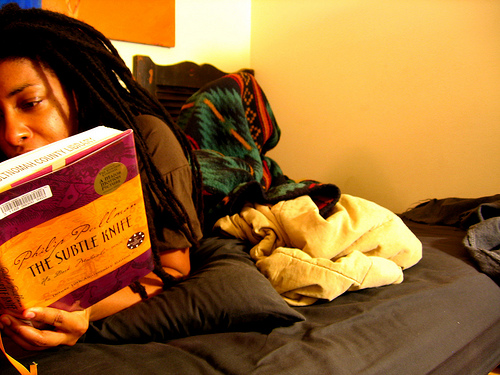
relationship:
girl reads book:
[0, 4, 211, 369] [0, 111, 162, 346]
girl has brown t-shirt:
[0, 4, 211, 369] [105, 111, 213, 251]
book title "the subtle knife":
[0, 111, 162, 346] [22, 211, 141, 282]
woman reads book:
[0, 4, 211, 369] [0, 111, 162, 346]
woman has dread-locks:
[0, 4, 211, 369] [1, 2, 208, 303]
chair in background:
[123, 46, 272, 133] [67, 6, 493, 93]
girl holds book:
[0, 4, 211, 369] [0, 111, 162, 346]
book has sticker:
[0, 111, 162, 346] [88, 160, 131, 198]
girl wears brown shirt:
[0, 4, 211, 369] [105, 111, 213, 251]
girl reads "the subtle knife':
[0, 4, 211, 369] [22, 211, 141, 282]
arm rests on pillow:
[71, 117, 210, 349] [51, 226, 310, 355]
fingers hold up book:
[2, 292, 97, 368] [0, 111, 162, 346]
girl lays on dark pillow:
[0, 4, 211, 369] [51, 226, 310, 355]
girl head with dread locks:
[0, 4, 133, 197] [0, 4, 211, 369]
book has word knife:
[0, 111, 162, 346] [97, 210, 139, 245]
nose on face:
[1, 106, 36, 150] [0, 45, 81, 163]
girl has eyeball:
[0, 4, 211, 369] [20, 96, 42, 111]